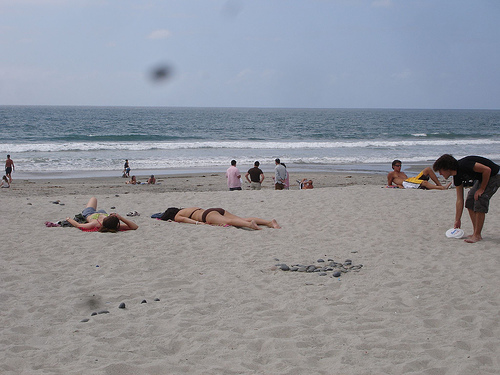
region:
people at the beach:
[0, 17, 497, 372]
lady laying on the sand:
[146, 182, 285, 239]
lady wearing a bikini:
[148, 188, 303, 247]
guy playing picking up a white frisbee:
[401, 137, 498, 251]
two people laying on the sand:
[34, 179, 285, 254]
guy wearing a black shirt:
[431, 142, 499, 254]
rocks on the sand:
[257, 232, 378, 302]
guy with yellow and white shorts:
[381, 151, 445, 200]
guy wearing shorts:
[434, 144, 499, 258]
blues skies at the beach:
[0, 0, 499, 374]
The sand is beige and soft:
[185, 282, 453, 363]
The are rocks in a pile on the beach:
[268, 251, 363, 286]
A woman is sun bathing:
[159, 204, 286, 237]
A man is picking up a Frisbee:
[431, 145, 498, 247]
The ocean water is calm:
[49, 107, 415, 129]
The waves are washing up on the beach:
[30, 131, 366, 165]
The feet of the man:
[461, 224, 486, 250]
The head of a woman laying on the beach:
[97, 211, 123, 236]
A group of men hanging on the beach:
[223, 153, 293, 191]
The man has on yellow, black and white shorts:
[401, 163, 431, 194]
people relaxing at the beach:
[0, 150, 499, 245]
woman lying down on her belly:
[158, 204, 282, 232]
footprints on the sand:
[276, 247, 362, 281]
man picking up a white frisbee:
[446, 220, 466, 240]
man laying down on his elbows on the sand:
[386, 159, 453, 191]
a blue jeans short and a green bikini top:
[81, 203, 112, 223]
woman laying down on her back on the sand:
[66, 197, 139, 231]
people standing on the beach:
[225, 158, 291, 193]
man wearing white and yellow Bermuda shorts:
[404, 167, 431, 192]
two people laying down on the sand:
[125, 172, 159, 185]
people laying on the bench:
[51, 189, 293, 244]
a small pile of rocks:
[286, 246, 351, 288]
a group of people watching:
[221, 143, 303, 191]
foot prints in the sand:
[153, 307, 432, 362]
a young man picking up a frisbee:
[431, 143, 493, 258]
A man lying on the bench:
[383, 159, 450, 207]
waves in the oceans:
[3, 132, 495, 157]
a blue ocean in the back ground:
[15, 106, 498, 146]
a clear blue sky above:
[18, 24, 478, 99]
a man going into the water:
[3, 153, 30, 188]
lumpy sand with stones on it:
[245, 248, 417, 330]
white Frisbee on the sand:
[425, 227, 463, 250]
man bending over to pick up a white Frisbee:
[432, 151, 499, 268]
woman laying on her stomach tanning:
[146, 196, 294, 246]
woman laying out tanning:
[33, 193, 297, 245]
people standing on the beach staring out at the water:
[192, 79, 337, 202]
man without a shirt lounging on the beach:
[375, 153, 434, 192]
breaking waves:
[248, 97, 495, 153]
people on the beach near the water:
[106, 124, 173, 193]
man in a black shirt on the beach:
[243, 134, 269, 211]